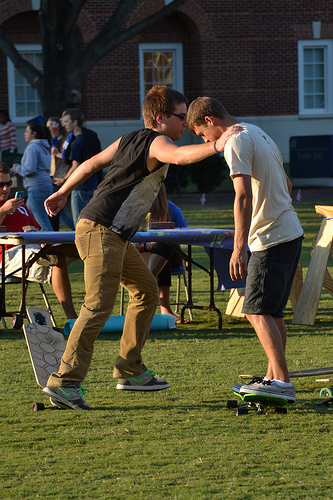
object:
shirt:
[224, 122, 305, 254]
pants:
[46, 219, 160, 386]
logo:
[58, 386, 71, 397]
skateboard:
[226, 400, 287, 417]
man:
[186, 96, 304, 404]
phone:
[220, 284, 226, 291]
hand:
[229, 249, 248, 281]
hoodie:
[16, 139, 53, 191]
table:
[148, 228, 234, 250]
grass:
[0, 203, 333, 499]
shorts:
[241, 233, 306, 317]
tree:
[0, 0, 185, 117]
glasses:
[171, 113, 184, 119]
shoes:
[43, 363, 170, 415]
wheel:
[32, 402, 45, 411]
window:
[297, 38, 333, 115]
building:
[0, 1, 333, 179]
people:
[12, 108, 102, 232]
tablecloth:
[0, 243, 58, 285]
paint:
[143, 243, 183, 287]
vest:
[60, 132, 73, 160]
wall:
[82, 0, 142, 120]